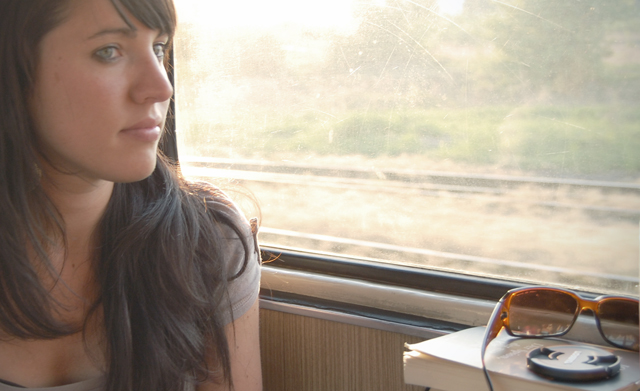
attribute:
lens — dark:
[602, 297, 620, 343]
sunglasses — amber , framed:
[478, 282, 618, 387]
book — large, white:
[394, 321, 618, 389]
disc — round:
[525, 337, 620, 384]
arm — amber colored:
[475, 293, 511, 389]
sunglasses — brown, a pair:
[455, 269, 638, 385]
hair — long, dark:
[63, 8, 239, 389]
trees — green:
[226, 10, 627, 174]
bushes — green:
[230, 95, 639, 181]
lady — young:
[0, 1, 253, 388]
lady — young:
[0, 8, 289, 386]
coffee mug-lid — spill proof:
[522, 335, 632, 389]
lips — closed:
[97, 115, 186, 149]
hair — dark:
[85, 159, 272, 376]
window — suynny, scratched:
[160, 16, 639, 285]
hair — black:
[51, 114, 308, 379]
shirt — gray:
[37, 229, 298, 357]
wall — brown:
[255, 302, 421, 389]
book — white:
[376, 311, 608, 388]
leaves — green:
[511, 22, 590, 126]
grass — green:
[407, 100, 639, 184]